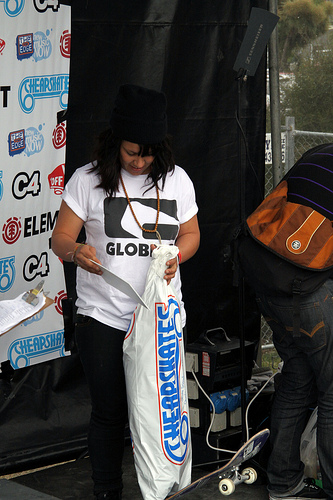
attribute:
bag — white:
[120, 241, 193, 498]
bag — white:
[114, 235, 198, 499]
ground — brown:
[288, 79, 306, 111]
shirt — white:
[43, 134, 216, 340]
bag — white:
[112, 237, 190, 498]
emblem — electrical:
[6, 123, 32, 152]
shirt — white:
[63, 158, 197, 333]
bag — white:
[140, 286, 184, 386]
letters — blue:
[151, 324, 179, 364]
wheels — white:
[240, 466, 257, 484]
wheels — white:
[217, 477, 236, 494]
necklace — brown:
[112, 168, 165, 247]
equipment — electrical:
[64, 0, 279, 467]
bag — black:
[241, 183, 329, 272]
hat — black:
[110, 93, 172, 143]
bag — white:
[124, 242, 208, 498]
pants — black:
[68, 311, 127, 499]